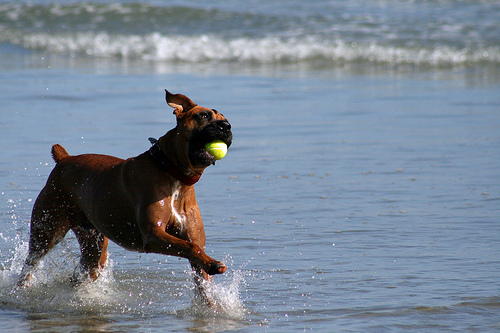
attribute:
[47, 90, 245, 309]
dog — brown, running, wet, shorthaired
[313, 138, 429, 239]
water — shallow, mild, splashing, small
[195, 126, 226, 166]
ball — yellow, green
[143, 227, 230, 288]
leg — brown, wet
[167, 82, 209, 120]
ear — wet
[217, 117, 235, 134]
nose — black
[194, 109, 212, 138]
eye — brown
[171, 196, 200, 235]
chest — white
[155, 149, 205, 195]
collar — red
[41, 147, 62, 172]
tail — small, brown